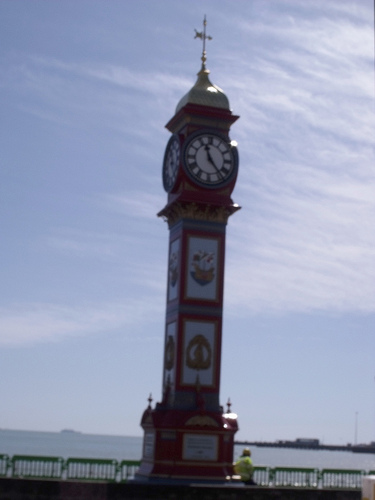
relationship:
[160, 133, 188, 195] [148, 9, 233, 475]
clock on tower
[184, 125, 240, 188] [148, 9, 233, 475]
clock on tower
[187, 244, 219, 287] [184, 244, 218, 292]
drawing on clock pillar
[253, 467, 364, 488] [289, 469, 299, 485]
barrier with bar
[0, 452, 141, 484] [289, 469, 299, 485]
barrier with bar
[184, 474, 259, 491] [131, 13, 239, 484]
reflection on tower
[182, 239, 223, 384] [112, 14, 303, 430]
decorations on tower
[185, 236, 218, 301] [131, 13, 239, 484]
drawing painted on tower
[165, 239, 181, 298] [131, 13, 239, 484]
picture painted on tower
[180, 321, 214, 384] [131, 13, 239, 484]
picture painted on tower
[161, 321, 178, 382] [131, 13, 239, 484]
picture painted on tower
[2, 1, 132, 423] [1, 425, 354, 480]
sky above ocean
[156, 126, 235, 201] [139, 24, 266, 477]
clock near top of tower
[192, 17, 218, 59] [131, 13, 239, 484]
vane on top of tower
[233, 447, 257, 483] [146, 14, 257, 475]
man sitting by tower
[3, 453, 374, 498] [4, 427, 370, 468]
pier next to ocean